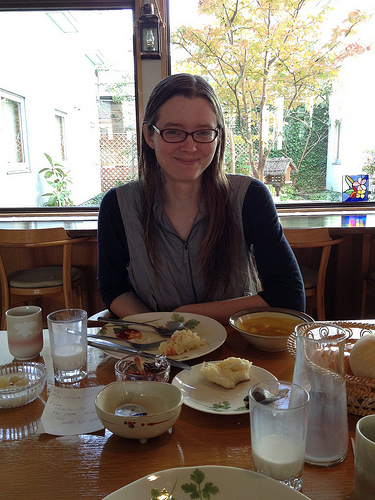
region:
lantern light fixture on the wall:
[133, 1, 165, 59]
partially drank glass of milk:
[248, 378, 309, 485]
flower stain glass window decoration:
[340, 172, 370, 203]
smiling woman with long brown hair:
[93, 68, 320, 310]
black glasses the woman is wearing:
[145, 115, 226, 146]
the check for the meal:
[34, 384, 107, 437]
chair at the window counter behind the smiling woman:
[0, 225, 92, 306]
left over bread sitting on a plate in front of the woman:
[197, 352, 252, 391]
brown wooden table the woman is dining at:
[2, 436, 100, 498]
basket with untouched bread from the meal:
[347, 317, 373, 415]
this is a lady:
[89, 69, 302, 302]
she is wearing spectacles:
[158, 122, 215, 143]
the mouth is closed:
[174, 152, 200, 164]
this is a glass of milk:
[249, 381, 307, 473]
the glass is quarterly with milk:
[252, 382, 303, 471]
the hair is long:
[211, 164, 234, 253]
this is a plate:
[204, 318, 221, 339]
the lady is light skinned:
[175, 178, 191, 194]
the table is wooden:
[34, 451, 90, 475]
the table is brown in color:
[42, 437, 102, 465]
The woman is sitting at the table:
[109, 70, 330, 316]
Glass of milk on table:
[241, 378, 321, 498]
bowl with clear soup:
[98, 370, 191, 440]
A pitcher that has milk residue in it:
[279, 310, 364, 465]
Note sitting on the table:
[37, 380, 122, 458]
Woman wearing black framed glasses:
[131, 93, 227, 170]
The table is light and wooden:
[15, 449, 76, 486]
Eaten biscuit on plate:
[188, 354, 273, 408]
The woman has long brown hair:
[114, 66, 249, 271]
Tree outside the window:
[180, 16, 372, 119]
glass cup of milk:
[47, 307, 88, 385]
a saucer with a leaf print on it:
[171, 358, 281, 415]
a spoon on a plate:
[96, 316, 186, 335]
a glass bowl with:
[0, 361, 48, 409]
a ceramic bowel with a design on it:
[94, 379, 185, 445]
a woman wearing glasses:
[149, 120, 223, 144]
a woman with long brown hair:
[139, 72, 239, 301]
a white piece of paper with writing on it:
[31, 383, 108, 437]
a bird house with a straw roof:
[262, 155, 299, 191]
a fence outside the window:
[99, 131, 140, 193]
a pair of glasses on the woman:
[158, 120, 216, 146]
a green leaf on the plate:
[181, 470, 216, 498]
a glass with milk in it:
[245, 383, 309, 492]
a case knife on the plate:
[83, 328, 191, 368]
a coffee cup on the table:
[0, 309, 46, 357]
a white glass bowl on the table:
[93, 378, 179, 446]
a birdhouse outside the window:
[260, 155, 295, 196]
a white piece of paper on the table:
[36, 381, 102, 442]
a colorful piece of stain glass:
[334, 171, 372, 205]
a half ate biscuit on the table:
[200, 356, 250, 391]